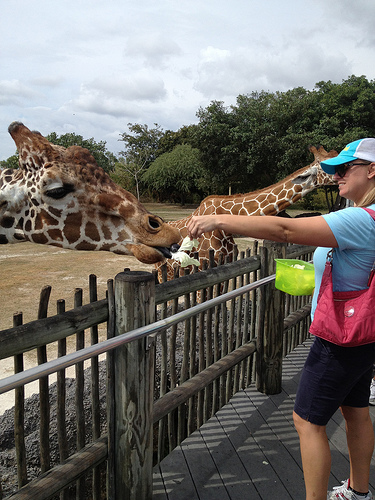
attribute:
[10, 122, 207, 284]
giraffe — eating, eating lettuce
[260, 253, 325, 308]
object — green, plastic container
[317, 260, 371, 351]
purse — pink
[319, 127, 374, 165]
hat — blue, white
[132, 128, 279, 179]
forest — green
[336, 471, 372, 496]
shoe — white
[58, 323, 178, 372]
fence — metal, brown, wooden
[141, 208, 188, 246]
nose — big as hand, big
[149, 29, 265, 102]
cloud — gray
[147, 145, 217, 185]
bush — green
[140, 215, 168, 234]
big nostril — dark, deep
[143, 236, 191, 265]
tongue — black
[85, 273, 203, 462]
post — brown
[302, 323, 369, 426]
shorts — black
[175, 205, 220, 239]
hand — raised, white